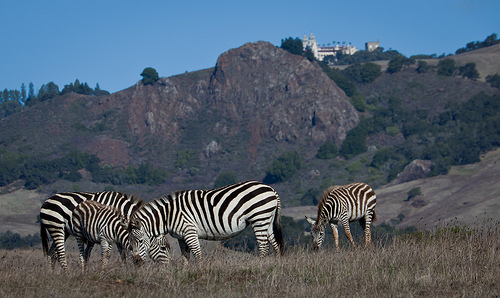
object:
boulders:
[0, 72, 183, 167]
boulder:
[195, 40, 360, 150]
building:
[291, 21, 361, 71]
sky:
[0, 0, 500, 94]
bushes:
[417, 137, 450, 176]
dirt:
[403, 181, 473, 211]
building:
[363, 37, 381, 51]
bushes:
[375, 47, 409, 63]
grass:
[2, 211, 500, 294]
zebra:
[297, 179, 383, 262]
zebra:
[106, 178, 287, 269]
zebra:
[66, 190, 150, 275]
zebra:
[33, 189, 170, 282]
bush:
[339, 119, 370, 163]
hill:
[270, 76, 484, 211]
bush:
[262, 149, 312, 188]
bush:
[280, 35, 304, 55]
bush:
[367, 148, 390, 169]